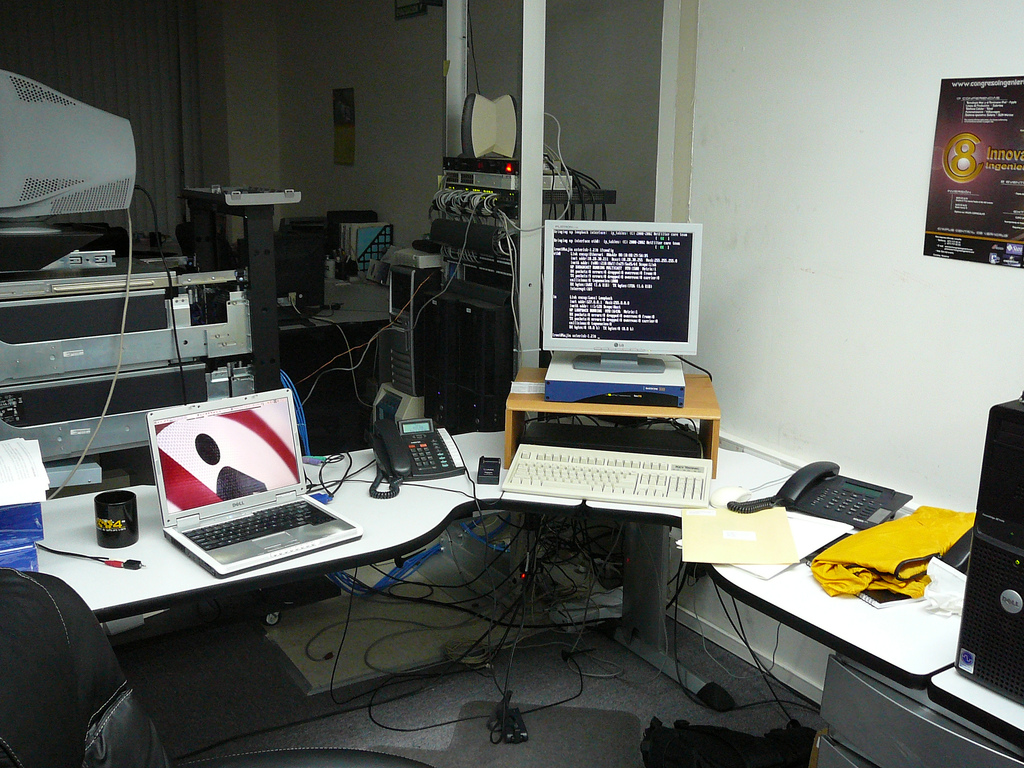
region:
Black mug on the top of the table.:
[96, 470, 139, 525]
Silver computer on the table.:
[134, 388, 379, 569]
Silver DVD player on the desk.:
[433, 148, 588, 203]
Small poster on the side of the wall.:
[918, 66, 1020, 300]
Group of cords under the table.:
[468, 534, 596, 686]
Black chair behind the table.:
[11, 555, 122, 745]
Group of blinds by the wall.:
[111, 34, 169, 63]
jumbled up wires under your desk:
[320, 499, 837, 750]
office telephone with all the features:
[727, 449, 921, 544]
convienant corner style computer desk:
[3, 386, 1021, 760]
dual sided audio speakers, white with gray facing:
[455, 86, 529, 164]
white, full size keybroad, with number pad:
[497, 437, 716, 515]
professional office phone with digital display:
[361, 411, 473, 485]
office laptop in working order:
[140, 382, 368, 582]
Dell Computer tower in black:
[951, 389, 1022, 723]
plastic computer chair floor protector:
[355, 689, 673, 765]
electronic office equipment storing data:
[1, 149, 1023, 709]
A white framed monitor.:
[540, 215, 703, 358]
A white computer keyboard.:
[499, 428, 733, 505]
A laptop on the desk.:
[137, 383, 372, 580]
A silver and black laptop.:
[112, 374, 379, 578]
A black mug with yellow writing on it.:
[98, 478, 150, 551]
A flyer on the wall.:
[896, 71, 1021, 294]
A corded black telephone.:
[356, 398, 502, 504]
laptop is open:
[140, 392, 375, 579]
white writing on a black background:
[555, 228, 691, 342]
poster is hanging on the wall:
[917, 63, 1023, 272]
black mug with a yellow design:
[93, 484, 144, 545]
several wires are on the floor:
[321, 506, 907, 764]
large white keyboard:
[492, 440, 733, 520]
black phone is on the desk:
[725, 444, 922, 544]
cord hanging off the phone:
[365, 472, 403, 502]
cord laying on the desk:
[36, 540, 144, 580]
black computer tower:
[952, 390, 1023, 705]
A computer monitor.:
[545, 218, 700, 406]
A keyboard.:
[498, 437, 711, 511]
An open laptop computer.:
[143, 385, 363, 582]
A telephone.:
[728, 456, 913, 536]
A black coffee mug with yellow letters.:
[93, 489, 142, 550]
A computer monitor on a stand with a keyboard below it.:
[501, 212, 732, 530]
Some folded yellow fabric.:
[811, 486, 977, 604]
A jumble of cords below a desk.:
[305, 509, 818, 741]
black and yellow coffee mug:
[93, 490, 141, 549]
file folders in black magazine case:
[336, 215, 397, 277]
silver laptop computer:
[143, 385, 363, 578]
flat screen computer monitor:
[541, 217, 703, 376]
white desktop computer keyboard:
[498, 439, 714, 512]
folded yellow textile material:
[810, 504, 981, 594]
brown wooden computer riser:
[501, 361, 720, 478]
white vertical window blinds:
[1, 2, 201, 241]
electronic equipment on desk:
[40, 533, 152, 579]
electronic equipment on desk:
[344, 401, 475, 506]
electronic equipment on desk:
[533, 196, 707, 409]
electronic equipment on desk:
[496, 424, 713, 516]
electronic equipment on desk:
[723, 424, 921, 545]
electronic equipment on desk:
[958, 372, 1022, 701]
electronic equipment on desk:
[312, 480, 347, 510]